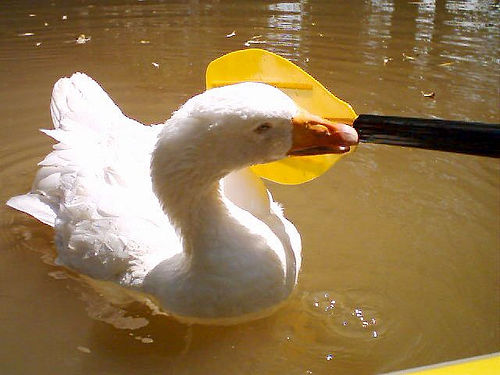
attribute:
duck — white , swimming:
[33, 43, 367, 340]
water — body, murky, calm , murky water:
[1, 1, 499, 373]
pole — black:
[354, 112, 499, 157]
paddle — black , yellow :
[204, 47, 498, 187]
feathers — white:
[109, 178, 196, 263]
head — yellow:
[119, 44, 331, 193]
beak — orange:
[286, 107, 361, 156]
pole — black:
[296, 80, 496, 177]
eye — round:
[254, 121, 274, 135]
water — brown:
[299, 194, 427, 324]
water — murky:
[350, 206, 455, 264]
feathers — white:
[95, 158, 136, 207]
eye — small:
[255, 116, 275, 133]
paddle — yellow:
[207, 47, 359, 184]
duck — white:
[181, 60, 271, 175]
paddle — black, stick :
[180, 33, 495, 190]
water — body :
[0, 5, 497, 49]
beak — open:
[289, 108, 361, 161]